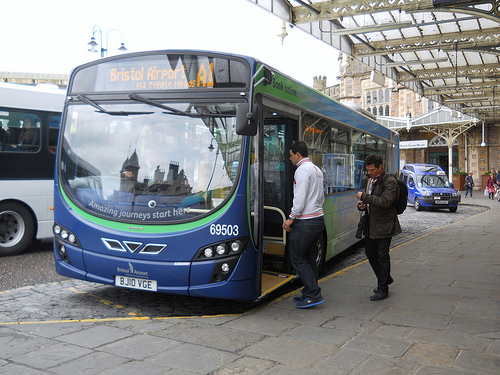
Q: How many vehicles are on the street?
A: 3.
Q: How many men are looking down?
A: 1.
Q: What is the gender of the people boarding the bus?
A: Male.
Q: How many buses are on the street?
A: 2.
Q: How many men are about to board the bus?
A: 2.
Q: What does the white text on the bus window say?
A: Amazing journeys start here.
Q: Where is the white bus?
A: Next to the blue bus.